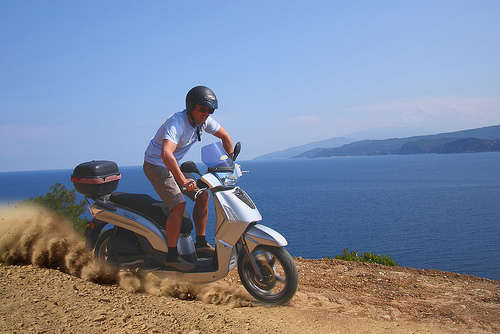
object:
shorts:
[138, 162, 194, 208]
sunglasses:
[200, 106, 215, 114]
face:
[187, 92, 220, 127]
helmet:
[185, 83, 219, 110]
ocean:
[0, 148, 500, 266]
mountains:
[311, 113, 500, 158]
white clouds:
[380, 92, 485, 132]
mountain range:
[313, 122, 496, 150]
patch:
[330, 245, 400, 266]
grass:
[333, 247, 396, 266]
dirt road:
[3, 231, 498, 332]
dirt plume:
[0, 199, 255, 309]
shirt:
[142, 109, 222, 172]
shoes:
[162, 249, 195, 267]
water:
[0, 150, 500, 260]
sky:
[4, 3, 499, 169]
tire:
[236, 242, 304, 311]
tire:
[93, 223, 145, 291]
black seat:
[107, 190, 193, 237]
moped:
[69, 141, 298, 306]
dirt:
[0, 195, 92, 278]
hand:
[184, 177, 199, 193]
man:
[137, 81, 234, 259]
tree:
[18, 177, 95, 253]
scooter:
[70, 141, 299, 304]